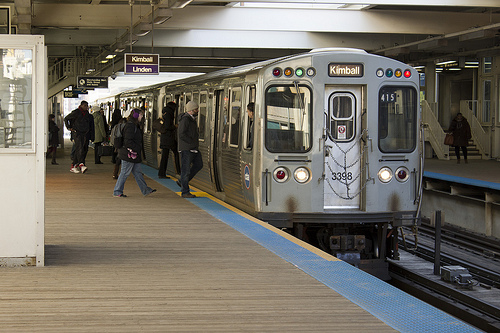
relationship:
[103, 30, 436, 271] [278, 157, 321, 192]
train has light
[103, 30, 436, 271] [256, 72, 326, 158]
train has windshield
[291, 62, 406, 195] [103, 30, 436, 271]
front of train